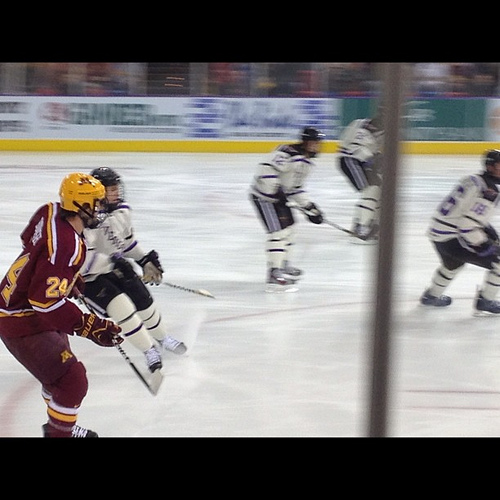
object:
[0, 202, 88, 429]
uniform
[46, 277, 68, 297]
number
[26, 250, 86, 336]
sleeve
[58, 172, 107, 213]
helmet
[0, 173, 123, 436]
hockey player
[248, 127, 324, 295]
hockey player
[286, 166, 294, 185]
white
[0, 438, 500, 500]
black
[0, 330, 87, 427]
pants leg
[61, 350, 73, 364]
m logo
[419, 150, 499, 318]
player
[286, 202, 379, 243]
hockey stick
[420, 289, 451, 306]
skates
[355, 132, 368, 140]
number 6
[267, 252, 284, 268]
socks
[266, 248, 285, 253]
stripes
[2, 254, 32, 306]
number 4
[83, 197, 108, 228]
cage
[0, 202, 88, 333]
jersey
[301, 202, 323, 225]
gloves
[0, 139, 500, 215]
rink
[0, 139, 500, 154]
yellow stripe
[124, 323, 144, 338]
stripes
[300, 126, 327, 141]
helmet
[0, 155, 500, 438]
floor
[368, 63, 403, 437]
pole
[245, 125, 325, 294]
man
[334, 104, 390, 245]
men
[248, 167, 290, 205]
hunched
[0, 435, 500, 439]
edge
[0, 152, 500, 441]
arena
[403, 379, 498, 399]
ice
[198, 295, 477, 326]
scratch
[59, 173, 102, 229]
head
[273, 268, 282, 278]
laces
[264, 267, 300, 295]
ice skating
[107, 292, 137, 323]
shin guards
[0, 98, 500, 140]
blackboard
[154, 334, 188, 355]
ice skates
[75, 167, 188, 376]
players